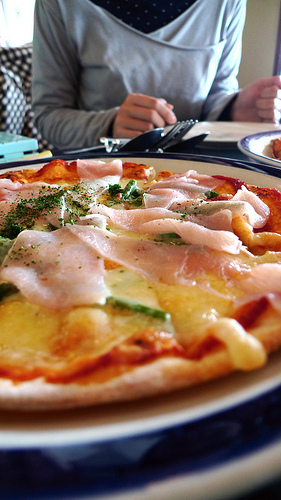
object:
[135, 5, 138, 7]
dot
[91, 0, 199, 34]
shirt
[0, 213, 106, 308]
ham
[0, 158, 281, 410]
pizza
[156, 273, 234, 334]
pineapple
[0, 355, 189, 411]
crust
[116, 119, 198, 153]
fork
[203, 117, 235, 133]
table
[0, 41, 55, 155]
sofa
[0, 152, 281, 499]
plate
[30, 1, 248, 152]
sweater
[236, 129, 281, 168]
bowl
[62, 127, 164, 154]
spoon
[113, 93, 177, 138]
fingers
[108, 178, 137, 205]
broccoli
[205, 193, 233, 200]
sauce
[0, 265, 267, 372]
cheese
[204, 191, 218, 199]
dish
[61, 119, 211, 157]
utensils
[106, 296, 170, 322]
herbs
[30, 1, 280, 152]
woman